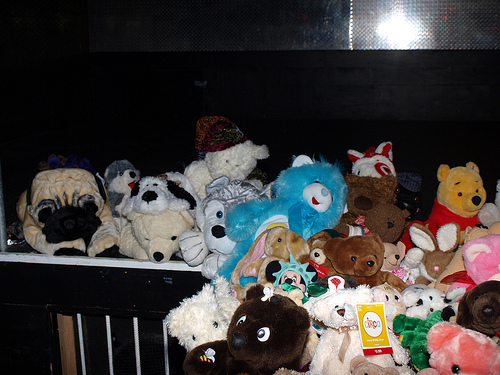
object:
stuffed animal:
[400, 282, 466, 320]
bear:
[413, 320, 499, 373]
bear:
[183, 284, 311, 373]